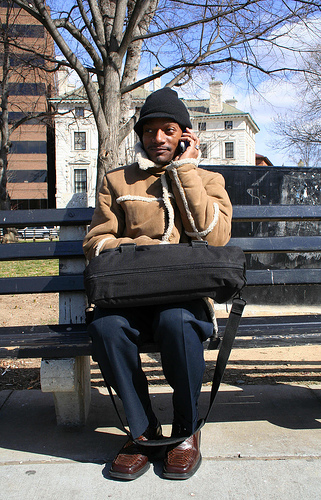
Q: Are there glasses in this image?
A: No, there are no glasses.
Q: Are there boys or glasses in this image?
A: No, there are no glasses or boys.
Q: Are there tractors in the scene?
A: No, there are no tractors.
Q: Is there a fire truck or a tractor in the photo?
A: No, there are no tractors or fire trucks.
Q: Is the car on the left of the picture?
A: Yes, the car is on the left of the image.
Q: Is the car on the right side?
A: No, the car is on the left of the image.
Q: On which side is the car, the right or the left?
A: The car is on the left of the image.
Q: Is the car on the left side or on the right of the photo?
A: The car is on the left of the image.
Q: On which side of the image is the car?
A: The car is on the left of the image.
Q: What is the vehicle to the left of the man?
A: The vehicle is a car.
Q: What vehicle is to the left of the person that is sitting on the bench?
A: The vehicle is a car.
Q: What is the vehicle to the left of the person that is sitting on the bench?
A: The vehicle is a car.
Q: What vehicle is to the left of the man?
A: The vehicle is a car.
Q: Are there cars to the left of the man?
A: Yes, there is a car to the left of the man.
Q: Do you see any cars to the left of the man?
A: Yes, there is a car to the left of the man.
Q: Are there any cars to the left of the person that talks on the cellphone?
A: Yes, there is a car to the left of the man.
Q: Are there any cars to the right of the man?
A: No, the car is to the left of the man.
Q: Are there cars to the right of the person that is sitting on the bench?
A: No, the car is to the left of the man.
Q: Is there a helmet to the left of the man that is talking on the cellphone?
A: No, there is a car to the left of the man.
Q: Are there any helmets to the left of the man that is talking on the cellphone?
A: No, there is a car to the left of the man.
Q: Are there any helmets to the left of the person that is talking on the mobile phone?
A: No, there is a car to the left of the man.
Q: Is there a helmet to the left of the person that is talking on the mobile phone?
A: No, there is a car to the left of the man.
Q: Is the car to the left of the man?
A: Yes, the car is to the left of the man.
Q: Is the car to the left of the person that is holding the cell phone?
A: Yes, the car is to the left of the man.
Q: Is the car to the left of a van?
A: No, the car is to the left of the man.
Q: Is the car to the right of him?
A: No, the car is to the left of the man.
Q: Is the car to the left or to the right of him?
A: The car is to the left of the man.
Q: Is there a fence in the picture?
A: No, there are no fences.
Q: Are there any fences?
A: No, there are no fences.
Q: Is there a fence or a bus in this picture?
A: No, there are no fences or buses.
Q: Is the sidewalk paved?
A: Yes, the sidewalk is paved.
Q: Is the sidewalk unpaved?
A: No, the sidewalk is paved.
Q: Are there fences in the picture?
A: No, there are no fences.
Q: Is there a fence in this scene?
A: No, there are no fences.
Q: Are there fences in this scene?
A: No, there are no fences.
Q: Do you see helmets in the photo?
A: No, there are no helmets.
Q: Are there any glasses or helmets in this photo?
A: No, there are no helmets or glasses.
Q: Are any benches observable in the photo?
A: Yes, there is a bench.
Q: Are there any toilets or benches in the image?
A: Yes, there is a bench.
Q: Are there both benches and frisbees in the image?
A: No, there is a bench but no frisbees.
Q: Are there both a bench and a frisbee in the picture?
A: No, there is a bench but no frisbees.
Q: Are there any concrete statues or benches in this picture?
A: Yes, there is a concrete bench.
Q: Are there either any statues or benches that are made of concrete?
A: Yes, the bench is made of concrete.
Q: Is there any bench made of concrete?
A: Yes, there is a bench that is made of concrete.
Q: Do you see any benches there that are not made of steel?
A: Yes, there is a bench that is made of concrete.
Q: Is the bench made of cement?
A: Yes, the bench is made of cement.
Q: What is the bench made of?
A: The bench is made of concrete.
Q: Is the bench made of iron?
A: No, the bench is made of cement.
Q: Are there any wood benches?
A: No, there is a bench but it is made of concrete.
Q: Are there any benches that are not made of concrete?
A: No, there is a bench but it is made of concrete.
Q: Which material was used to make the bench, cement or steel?
A: The bench is made of cement.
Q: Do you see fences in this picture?
A: No, there are no fences.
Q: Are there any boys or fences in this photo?
A: No, there are no fences or boys.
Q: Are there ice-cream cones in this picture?
A: No, there are no ice-cream cones.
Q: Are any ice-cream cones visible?
A: No, there are no ice-cream cones.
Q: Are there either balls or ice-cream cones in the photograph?
A: No, there are no ice-cream cones or balls.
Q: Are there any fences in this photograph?
A: No, there are no fences.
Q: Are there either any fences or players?
A: No, there are no fences or players.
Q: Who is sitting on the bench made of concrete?
A: The man is sitting on the bench.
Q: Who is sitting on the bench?
A: The man is sitting on the bench.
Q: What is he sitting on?
A: The man is sitting on the bench.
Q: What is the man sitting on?
A: The man is sitting on the bench.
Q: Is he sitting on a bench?
A: Yes, the man is sitting on a bench.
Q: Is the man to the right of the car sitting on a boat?
A: No, the man is sitting on a bench.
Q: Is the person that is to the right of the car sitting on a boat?
A: No, the man is sitting on a bench.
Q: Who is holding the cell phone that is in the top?
A: The man is holding the mobile phone.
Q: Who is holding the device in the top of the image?
A: The man is holding the mobile phone.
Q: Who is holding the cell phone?
A: The man is holding the mobile phone.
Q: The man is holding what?
A: The man is holding the cellphone.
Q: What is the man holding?
A: The man is holding the cellphone.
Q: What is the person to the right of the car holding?
A: The man is holding the cellphone.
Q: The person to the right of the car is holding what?
A: The man is holding the cellphone.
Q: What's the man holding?
A: The man is holding the cellphone.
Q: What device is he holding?
A: The man is holding the mobile phone.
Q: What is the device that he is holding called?
A: The device is a cell phone.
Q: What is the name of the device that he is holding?
A: The device is a cell phone.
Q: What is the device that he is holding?
A: The device is a cell phone.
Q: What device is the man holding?
A: The man is holding the mobile phone.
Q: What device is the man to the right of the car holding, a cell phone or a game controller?
A: The man is holding a cell phone.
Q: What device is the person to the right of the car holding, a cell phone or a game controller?
A: The man is holding a cell phone.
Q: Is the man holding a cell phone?
A: Yes, the man is holding a cell phone.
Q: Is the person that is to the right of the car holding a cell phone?
A: Yes, the man is holding a cell phone.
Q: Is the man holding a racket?
A: No, the man is holding a cell phone.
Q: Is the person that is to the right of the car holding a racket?
A: No, the man is holding a cell phone.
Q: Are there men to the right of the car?
A: Yes, there is a man to the right of the car.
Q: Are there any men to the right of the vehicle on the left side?
A: Yes, there is a man to the right of the car.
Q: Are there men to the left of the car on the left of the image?
A: No, the man is to the right of the car.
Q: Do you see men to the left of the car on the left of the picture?
A: No, the man is to the right of the car.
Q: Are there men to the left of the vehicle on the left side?
A: No, the man is to the right of the car.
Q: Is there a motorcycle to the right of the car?
A: No, there is a man to the right of the car.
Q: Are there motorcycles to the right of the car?
A: No, there is a man to the right of the car.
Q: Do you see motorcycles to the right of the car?
A: No, there is a man to the right of the car.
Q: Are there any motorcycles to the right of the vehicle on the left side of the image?
A: No, there is a man to the right of the car.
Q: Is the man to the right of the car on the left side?
A: Yes, the man is to the right of the car.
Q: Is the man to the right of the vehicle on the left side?
A: Yes, the man is to the right of the car.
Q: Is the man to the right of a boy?
A: No, the man is to the right of the car.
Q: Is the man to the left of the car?
A: No, the man is to the right of the car.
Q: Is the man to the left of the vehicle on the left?
A: No, the man is to the right of the car.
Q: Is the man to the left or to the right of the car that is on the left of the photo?
A: The man is to the right of the car.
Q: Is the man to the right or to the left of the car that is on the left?
A: The man is to the right of the car.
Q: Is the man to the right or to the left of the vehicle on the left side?
A: The man is to the right of the car.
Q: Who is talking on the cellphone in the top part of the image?
A: The man is talking on the cellphone.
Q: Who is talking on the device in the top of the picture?
A: The man is talking on the cellphone.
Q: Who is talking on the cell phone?
A: The man is talking on the cellphone.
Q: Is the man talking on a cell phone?
A: Yes, the man is talking on a cell phone.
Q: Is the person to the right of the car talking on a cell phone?
A: Yes, the man is talking on a cell phone.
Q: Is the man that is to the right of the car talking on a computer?
A: No, the man is talking on a cell phone.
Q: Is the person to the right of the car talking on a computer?
A: No, the man is talking on a cell phone.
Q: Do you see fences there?
A: No, there are no fences.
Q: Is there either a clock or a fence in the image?
A: No, there are no fences or clocks.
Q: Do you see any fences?
A: No, there are no fences.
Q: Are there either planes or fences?
A: No, there are no fences or planes.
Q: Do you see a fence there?
A: No, there are no fences.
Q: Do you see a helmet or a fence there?
A: No, there are no fences or helmets.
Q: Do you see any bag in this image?
A: Yes, there is a bag.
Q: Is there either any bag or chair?
A: Yes, there is a bag.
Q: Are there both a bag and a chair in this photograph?
A: No, there is a bag but no chairs.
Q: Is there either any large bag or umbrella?
A: Yes, there is a large bag.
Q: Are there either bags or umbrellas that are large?
A: Yes, the bag is large.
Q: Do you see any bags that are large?
A: Yes, there is a large bag.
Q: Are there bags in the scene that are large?
A: Yes, there is a bag that is large.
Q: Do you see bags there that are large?
A: Yes, there is a bag that is large.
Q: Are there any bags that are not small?
A: Yes, there is a large bag.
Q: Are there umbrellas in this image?
A: No, there are no umbrellas.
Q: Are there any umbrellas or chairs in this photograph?
A: No, there are no umbrellas or chairs.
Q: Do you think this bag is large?
A: Yes, the bag is large.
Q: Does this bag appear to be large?
A: Yes, the bag is large.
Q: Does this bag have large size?
A: Yes, the bag is large.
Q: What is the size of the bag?
A: The bag is large.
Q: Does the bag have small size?
A: No, the bag is large.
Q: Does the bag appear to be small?
A: No, the bag is large.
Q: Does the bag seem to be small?
A: No, the bag is large.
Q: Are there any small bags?
A: No, there is a bag but it is large.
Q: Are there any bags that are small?
A: No, there is a bag but it is large.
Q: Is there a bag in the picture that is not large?
A: No, there is a bag but it is large.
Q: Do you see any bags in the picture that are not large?
A: No, there is a bag but it is large.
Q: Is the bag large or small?
A: The bag is large.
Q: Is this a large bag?
A: Yes, this is a large bag.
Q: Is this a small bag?
A: No, this is a large bag.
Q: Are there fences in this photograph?
A: No, there are no fences.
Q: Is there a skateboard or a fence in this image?
A: No, there are no fences or skateboards.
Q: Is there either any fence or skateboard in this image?
A: No, there are no fences or skateboards.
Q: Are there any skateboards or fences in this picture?
A: No, there are no fences or skateboards.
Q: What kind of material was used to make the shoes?
A: The shoes are made of leather.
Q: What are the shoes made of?
A: The shoes are made of leather.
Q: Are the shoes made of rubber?
A: No, the shoes are made of leather.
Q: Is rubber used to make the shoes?
A: No, the shoes are made of leather.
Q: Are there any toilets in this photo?
A: No, there are no toilets.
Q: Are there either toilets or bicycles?
A: No, there are no toilets or bicycles.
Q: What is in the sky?
A: The clouds are in the sky.